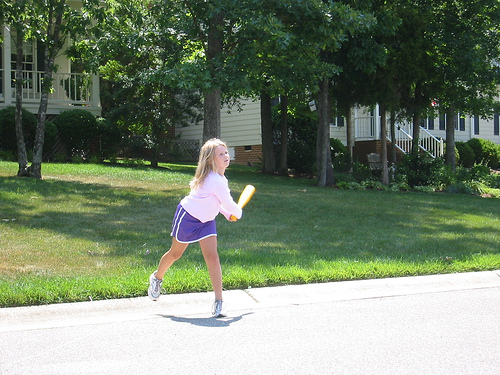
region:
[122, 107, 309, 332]
The girl is standing on the street.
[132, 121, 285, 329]
The girl is playing baseball.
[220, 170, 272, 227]
The girl holds a baseball bat.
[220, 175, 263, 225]
The baseball bat is yellow.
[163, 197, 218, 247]
The girl wears purple shorts.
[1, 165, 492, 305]
A lawn in behind the girl.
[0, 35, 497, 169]
Houses are behind the lawn.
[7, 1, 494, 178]
Trees are on the lawns.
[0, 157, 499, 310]
Sun shines on the lawn.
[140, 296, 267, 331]
The girl's shadow is on the street.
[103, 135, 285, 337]
little girl holding yellow plastic ball bat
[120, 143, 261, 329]
little girl wearing white sneakers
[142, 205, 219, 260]
little girl wearing purple athletic skirt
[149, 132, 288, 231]
little girl wearing white pullover jacket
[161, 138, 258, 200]
little girl with long blond hair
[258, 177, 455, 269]
beautiful grassy green yard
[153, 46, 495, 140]
white residential house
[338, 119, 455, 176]
white wooden steps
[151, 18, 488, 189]
several green trees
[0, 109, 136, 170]
several green shrubs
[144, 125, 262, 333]
Young girl will hit ball.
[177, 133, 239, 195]
Long blonde hair away face.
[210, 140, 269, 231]
Plastic baseball bat to strike.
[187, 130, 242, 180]
Concentrating ball being pitched.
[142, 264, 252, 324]
One foot raised one ding-toed.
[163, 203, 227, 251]
Purple short skirt white trim.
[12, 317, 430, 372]
Street road paved concrete.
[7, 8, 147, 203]
Shaded home porch railing.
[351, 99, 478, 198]
White stair railing leads door.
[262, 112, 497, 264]
Tree shadows cover green grass.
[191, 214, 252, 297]
Blue skirt on girl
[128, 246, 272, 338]
Girl wearing tennis shoes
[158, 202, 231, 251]
White stripe and edging on skirt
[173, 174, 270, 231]
Girl wearing white shirt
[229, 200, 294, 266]
Girl swinging bat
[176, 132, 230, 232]
Girl has long blonde hair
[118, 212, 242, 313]
Girl standing in road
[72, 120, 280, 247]
Green grass behind girl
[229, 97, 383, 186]
White house beyond trees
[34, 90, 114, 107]
White front porch railing on house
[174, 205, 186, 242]
White stripes on girl's skirt.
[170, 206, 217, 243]
Blue and white skirt.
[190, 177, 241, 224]
White sweater worn by the girl.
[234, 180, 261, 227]
Yellow bat in the girl's hand.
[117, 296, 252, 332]
Area where the girl is standing.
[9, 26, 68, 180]
Double barked tree behind the girl.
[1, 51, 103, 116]
White porch balcony of the house behind the girl.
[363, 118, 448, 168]
White stairs on the house on the right.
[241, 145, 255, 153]
Rectangle window on the brick basement of the right house.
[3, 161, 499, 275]
Green lawn behind the girl.